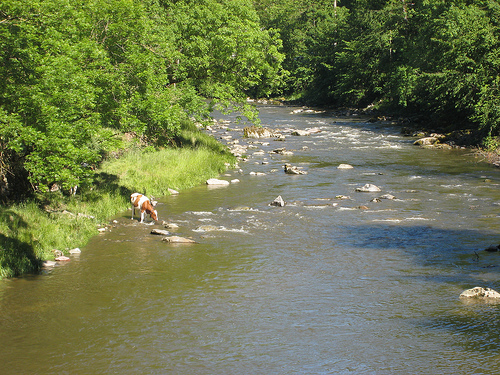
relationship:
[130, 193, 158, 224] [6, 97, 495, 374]
animal drinking from river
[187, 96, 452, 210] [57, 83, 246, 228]
rock next to grass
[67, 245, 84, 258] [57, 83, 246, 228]
rock next to grass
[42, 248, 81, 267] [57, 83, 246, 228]
rock next to grass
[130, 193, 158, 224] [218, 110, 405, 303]
animal by river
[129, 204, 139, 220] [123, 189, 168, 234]
leg on horse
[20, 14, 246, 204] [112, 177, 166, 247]
tree behind animal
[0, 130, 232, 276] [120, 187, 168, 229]
grass around animal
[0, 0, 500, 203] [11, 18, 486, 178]
tree in back ground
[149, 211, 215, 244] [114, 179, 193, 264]
rock closest to animal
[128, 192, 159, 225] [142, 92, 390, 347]
animal drinking water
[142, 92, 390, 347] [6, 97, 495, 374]
water from river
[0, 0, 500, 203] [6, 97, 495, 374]
tree around river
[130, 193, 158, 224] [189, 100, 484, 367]
animal drinking from water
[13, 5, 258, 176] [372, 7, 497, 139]
leaves covering trees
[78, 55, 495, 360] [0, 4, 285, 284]
river surrounded by forrest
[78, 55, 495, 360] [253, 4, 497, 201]
river surrounded by forrest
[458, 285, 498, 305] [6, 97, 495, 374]
rock in river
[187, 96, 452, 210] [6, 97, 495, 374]
rock in river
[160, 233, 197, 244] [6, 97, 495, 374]
rock in river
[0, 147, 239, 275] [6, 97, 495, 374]
grass along river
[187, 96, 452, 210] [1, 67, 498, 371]
rock in river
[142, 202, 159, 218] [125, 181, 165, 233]
neck of horse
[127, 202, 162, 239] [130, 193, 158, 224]
leg of animal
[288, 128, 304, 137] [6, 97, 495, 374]
rock in river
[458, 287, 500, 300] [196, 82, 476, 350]
rock in river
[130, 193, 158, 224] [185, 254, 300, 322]
animal by stream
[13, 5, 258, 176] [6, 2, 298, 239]
leaves on tree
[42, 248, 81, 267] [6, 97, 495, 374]
rock by river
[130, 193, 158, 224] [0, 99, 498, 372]
animal drinking from stream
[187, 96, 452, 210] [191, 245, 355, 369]
rock in middle of water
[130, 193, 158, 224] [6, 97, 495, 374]
animal in river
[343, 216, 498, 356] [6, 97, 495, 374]
shadow on river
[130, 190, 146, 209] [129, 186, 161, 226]
body of horse